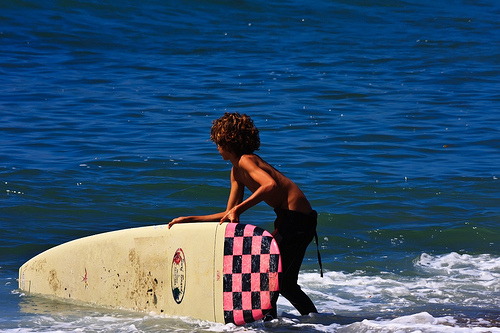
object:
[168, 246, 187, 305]
logo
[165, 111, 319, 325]
boy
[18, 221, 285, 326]
board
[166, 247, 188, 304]
circle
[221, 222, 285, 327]
checker design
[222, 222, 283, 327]
end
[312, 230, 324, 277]
drawstring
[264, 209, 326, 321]
black pants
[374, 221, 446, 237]
ripple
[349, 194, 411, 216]
ripple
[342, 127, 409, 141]
ripple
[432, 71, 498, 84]
ripple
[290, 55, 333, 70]
ripple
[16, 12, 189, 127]
ocean water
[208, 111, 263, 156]
curly hair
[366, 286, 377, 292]
froth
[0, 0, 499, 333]
water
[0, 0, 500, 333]
ocean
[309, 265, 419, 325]
water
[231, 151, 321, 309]
wetsuit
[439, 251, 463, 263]
foam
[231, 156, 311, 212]
torso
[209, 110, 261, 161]
head